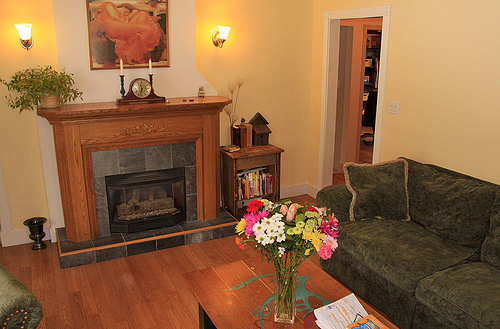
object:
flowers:
[317, 246, 333, 258]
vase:
[273, 270, 295, 323]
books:
[236, 169, 274, 199]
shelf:
[220, 139, 285, 217]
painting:
[86, 0, 170, 70]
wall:
[0, 0, 310, 248]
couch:
[317, 156, 499, 328]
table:
[182, 250, 400, 328]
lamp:
[211, 24, 233, 50]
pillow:
[341, 158, 411, 221]